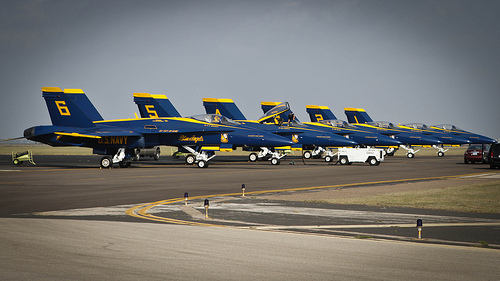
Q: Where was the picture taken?
A: It was taken at the road.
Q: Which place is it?
A: It is a road.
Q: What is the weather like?
A: It is cloudy.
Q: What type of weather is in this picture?
A: It is cloudy.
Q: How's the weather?
A: It is cloudy.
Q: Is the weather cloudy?
A: Yes, it is cloudy.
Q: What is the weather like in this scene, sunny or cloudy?
A: It is cloudy.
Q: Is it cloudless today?
A: No, it is cloudy.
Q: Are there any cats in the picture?
A: No, there are no cats.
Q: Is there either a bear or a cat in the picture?
A: No, there are no cats or bears.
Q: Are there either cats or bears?
A: No, there are no cats or bears.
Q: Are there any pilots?
A: No, there are no pilots.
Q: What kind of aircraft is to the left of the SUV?
A: The aircraft is a jet.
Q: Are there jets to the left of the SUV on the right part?
A: Yes, there is a jet to the left of the SUV.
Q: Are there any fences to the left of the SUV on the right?
A: No, there is a jet to the left of the SUV.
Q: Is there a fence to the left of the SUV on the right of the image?
A: No, there is a jet to the left of the SUV.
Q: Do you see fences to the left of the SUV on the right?
A: No, there is a jet to the left of the SUV.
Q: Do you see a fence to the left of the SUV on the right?
A: No, there is a jet to the left of the SUV.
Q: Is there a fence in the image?
A: No, there are no fences.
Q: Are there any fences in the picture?
A: No, there are no fences.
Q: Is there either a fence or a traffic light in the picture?
A: No, there are no fences or traffic lights.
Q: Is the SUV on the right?
A: Yes, the SUV is on the right of the image.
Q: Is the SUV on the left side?
A: No, the SUV is on the right of the image.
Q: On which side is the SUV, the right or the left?
A: The SUV is on the right of the image.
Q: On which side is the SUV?
A: The SUV is on the right of the image.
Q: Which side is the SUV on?
A: The SUV is on the right of the image.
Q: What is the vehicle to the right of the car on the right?
A: The vehicle is a SUV.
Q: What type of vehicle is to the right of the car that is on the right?
A: The vehicle is a SUV.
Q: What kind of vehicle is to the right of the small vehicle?
A: The vehicle is a SUV.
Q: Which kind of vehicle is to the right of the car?
A: The vehicle is a SUV.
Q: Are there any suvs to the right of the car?
A: Yes, there is a SUV to the right of the car.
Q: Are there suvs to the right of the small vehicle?
A: Yes, there is a SUV to the right of the car.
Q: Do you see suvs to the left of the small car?
A: No, the SUV is to the right of the car.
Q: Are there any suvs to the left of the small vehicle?
A: No, the SUV is to the right of the car.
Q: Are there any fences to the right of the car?
A: No, there is a SUV to the right of the car.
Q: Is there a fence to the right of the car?
A: No, there is a SUV to the right of the car.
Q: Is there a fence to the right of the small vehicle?
A: No, there is a SUV to the right of the car.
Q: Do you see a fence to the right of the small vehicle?
A: No, there is a SUV to the right of the car.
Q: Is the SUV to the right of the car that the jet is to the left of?
A: Yes, the SUV is to the right of the car.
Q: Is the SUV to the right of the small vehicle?
A: Yes, the SUV is to the right of the car.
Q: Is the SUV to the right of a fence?
A: No, the SUV is to the right of the car.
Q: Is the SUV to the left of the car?
A: No, the SUV is to the right of the car.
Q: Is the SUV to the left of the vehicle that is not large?
A: No, the SUV is to the right of the car.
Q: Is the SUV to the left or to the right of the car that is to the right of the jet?
A: The SUV is to the right of the car.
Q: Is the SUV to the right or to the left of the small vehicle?
A: The SUV is to the right of the car.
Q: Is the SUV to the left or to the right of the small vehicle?
A: The SUV is to the right of the car.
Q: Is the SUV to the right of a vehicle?
A: Yes, the SUV is to the right of a vehicle.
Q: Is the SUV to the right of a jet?
A: Yes, the SUV is to the right of a jet.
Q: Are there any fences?
A: No, there are no fences.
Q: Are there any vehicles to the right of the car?
A: Yes, there is a vehicle to the right of the car.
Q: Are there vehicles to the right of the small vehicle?
A: Yes, there is a vehicle to the right of the car.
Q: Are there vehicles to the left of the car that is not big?
A: No, the vehicle is to the right of the car.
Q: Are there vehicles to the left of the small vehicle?
A: No, the vehicle is to the right of the car.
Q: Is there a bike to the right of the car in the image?
A: No, there is a vehicle to the right of the car.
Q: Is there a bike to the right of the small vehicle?
A: No, there is a vehicle to the right of the car.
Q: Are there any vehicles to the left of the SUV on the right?
A: Yes, there is a vehicle to the left of the SUV.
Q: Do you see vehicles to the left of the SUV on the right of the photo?
A: Yes, there is a vehicle to the left of the SUV.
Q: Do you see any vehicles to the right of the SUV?
A: No, the vehicle is to the left of the SUV.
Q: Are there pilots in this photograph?
A: No, there are no pilots.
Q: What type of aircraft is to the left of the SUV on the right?
A: The aircraft is a jet.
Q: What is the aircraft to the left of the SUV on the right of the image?
A: The aircraft is a jet.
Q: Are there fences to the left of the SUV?
A: No, there is a jet to the left of the SUV.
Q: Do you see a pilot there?
A: No, there are no pilots.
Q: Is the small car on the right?
A: Yes, the car is on the right of the image.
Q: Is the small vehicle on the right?
A: Yes, the car is on the right of the image.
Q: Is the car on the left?
A: No, the car is on the right of the image.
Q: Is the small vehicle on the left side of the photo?
A: No, the car is on the right of the image.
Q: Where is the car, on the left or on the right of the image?
A: The car is on the right of the image.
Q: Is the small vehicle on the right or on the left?
A: The car is on the right of the image.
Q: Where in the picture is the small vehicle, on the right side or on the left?
A: The car is on the right of the image.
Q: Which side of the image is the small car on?
A: The car is on the right of the image.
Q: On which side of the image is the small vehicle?
A: The car is on the right of the image.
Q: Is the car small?
A: Yes, the car is small.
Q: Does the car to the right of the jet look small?
A: Yes, the car is small.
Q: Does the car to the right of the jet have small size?
A: Yes, the car is small.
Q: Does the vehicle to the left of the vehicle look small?
A: Yes, the car is small.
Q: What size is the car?
A: The car is small.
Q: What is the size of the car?
A: The car is small.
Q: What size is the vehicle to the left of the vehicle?
A: The car is small.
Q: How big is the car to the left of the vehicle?
A: The car is small.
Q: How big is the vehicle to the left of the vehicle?
A: The car is small.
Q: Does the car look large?
A: No, the car is small.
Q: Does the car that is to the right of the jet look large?
A: No, the car is small.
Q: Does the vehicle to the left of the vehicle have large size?
A: No, the car is small.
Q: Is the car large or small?
A: The car is small.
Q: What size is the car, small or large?
A: The car is small.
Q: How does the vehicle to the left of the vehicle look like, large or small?
A: The car is small.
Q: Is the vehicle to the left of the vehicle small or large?
A: The car is small.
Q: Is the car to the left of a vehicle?
A: Yes, the car is to the left of a vehicle.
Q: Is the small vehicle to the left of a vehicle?
A: Yes, the car is to the left of a vehicle.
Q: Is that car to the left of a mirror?
A: No, the car is to the left of a vehicle.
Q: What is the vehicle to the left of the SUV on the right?
A: The vehicle is a car.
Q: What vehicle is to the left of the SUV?
A: The vehicle is a car.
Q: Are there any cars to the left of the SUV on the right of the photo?
A: Yes, there is a car to the left of the SUV.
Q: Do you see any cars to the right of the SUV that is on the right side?
A: No, the car is to the left of the SUV.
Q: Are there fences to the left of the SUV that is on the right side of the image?
A: No, there is a car to the left of the SUV.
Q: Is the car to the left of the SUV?
A: Yes, the car is to the left of the SUV.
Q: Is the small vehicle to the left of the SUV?
A: Yes, the car is to the left of the SUV.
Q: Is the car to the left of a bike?
A: No, the car is to the left of the SUV.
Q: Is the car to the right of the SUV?
A: No, the car is to the left of the SUV.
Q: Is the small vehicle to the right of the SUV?
A: No, the car is to the left of the SUV.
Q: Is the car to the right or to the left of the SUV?
A: The car is to the left of the SUV.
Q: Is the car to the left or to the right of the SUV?
A: The car is to the left of the SUV.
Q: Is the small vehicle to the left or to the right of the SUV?
A: The car is to the left of the SUV.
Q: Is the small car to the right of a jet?
A: Yes, the car is to the right of a jet.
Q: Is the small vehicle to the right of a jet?
A: Yes, the car is to the right of a jet.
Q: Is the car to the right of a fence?
A: No, the car is to the right of a jet.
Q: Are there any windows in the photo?
A: Yes, there is a window.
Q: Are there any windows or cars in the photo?
A: Yes, there is a window.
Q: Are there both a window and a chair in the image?
A: No, there is a window but no chairs.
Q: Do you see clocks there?
A: No, there are no clocks.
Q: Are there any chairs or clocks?
A: No, there are no clocks or chairs.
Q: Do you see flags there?
A: No, there are no flags.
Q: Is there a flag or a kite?
A: No, there are no flags or kites.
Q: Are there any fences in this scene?
A: No, there are no fences.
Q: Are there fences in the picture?
A: No, there are no fences.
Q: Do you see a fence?
A: No, there are no fences.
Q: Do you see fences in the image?
A: No, there are no fences.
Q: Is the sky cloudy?
A: Yes, the sky is cloudy.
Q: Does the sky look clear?
A: No, the sky is cloudy.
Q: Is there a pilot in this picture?
A: No, there are no pilots.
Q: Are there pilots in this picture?
A: No, there are no pilots.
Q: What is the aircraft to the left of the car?
A: The aircraft is a jet.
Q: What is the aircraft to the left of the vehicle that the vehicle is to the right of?
A: The aircraft is a jet.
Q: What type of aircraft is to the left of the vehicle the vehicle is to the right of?
A: The aircraft is a jet.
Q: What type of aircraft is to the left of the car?
A: The aircraft is a jet.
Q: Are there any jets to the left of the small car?
A: Yes, there is a jet to the left of the car.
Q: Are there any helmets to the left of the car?
A: No, there is a jet to the left of the car.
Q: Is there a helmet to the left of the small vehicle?
A: No, there is a jet to the left of the car.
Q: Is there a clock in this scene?
A: No, there are no clocks.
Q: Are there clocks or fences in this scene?
A: No, there are no clocks or fences.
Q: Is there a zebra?
A: No, there are no zebras.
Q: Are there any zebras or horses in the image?
A: No, there are no zebras or horses.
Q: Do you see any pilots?
A: No, there are no pilots.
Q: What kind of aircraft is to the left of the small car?
A: The aircraft is a jet.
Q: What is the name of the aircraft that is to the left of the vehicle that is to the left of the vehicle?
A: The aircraft is a jet.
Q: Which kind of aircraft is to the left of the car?
A: The aircraft is a jet.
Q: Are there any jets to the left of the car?
A: Yes, there is a jet to the left of the car.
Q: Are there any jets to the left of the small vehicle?
A: Yes, there is a jet to the left of the car.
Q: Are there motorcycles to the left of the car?
A: No, there is a jet to the left of the car.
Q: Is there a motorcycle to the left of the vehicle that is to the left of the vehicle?
A: No, there is a jet to the left of the car.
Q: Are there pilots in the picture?
A: No, there are no pilots.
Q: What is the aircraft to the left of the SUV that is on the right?
A: The aircraft is a jet.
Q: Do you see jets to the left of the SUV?
A: Yes, there is a jet to the left of the SUV.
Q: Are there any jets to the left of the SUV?
A: Yes, there is a jet to the left of the SUV.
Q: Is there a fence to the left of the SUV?
A: No, there is a jet to the left of the SUV.